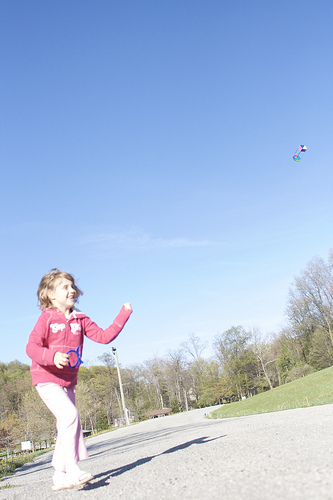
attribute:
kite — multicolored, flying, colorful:
[292, 145, 308, 161]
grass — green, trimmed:
[203, 366, 332, 419]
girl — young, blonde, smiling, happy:
[27, 268, 134, 493]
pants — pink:
[33, 384, 92, 470]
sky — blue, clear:
[1, 1, 333, 363]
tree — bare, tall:
[287, 253, 332, 363]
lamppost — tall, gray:
[111, 343, 132, 427]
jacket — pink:
[25, 307, 134, 386]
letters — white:
[48, 321, 82, 335]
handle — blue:
[66, 345, 84, 370]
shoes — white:
[49, 468, 94, 492]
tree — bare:
[159, 351, 189, 412]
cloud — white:
[98, 230, 226, 257]